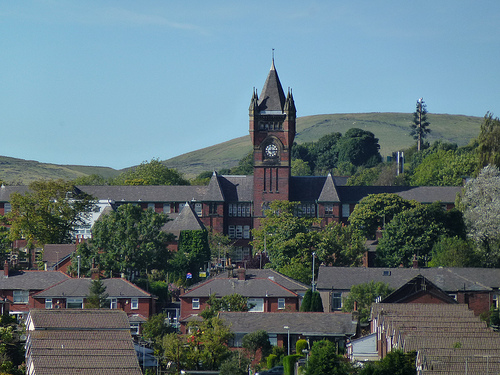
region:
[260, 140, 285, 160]
clock face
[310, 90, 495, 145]
flat green hills to horizon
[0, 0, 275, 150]
bright clear sky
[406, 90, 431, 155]
tall tree standing alone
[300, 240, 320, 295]
telephone pole in street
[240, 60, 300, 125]
clock tower roof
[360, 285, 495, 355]
row of houses in cul de sac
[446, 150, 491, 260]
white leaved tree standing alone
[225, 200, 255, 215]
row of windows on clock tower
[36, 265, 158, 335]
brick house in cul de sac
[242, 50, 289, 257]
a tall clock tower in front of the building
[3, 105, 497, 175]
grassy hills in the background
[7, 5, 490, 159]
the bright blue cloudless sky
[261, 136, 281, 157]
the clock in the tower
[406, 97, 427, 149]
a very tall tree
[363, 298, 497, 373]
a row of homes along a street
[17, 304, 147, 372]
another row of homes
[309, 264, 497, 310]
a big house in the neighborhood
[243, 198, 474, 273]
a group of green leafy trees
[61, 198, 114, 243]
a building with a white roof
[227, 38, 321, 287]
tall clock tower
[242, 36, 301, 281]
big red pointy tower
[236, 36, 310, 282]
red brick clock tower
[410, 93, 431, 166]
very tall tree on hillside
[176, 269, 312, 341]
red brick house with black shingle roof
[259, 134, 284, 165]
large black and white clock on tower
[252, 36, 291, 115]
pointed spire on top of clock tower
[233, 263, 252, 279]
chimney on roof of house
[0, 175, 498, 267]
large building attached to clock tower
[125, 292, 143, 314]
small white window in brick house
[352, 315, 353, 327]
edge of a roof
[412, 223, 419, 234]
edge of a plant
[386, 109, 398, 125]
part of a mountain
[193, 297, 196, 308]
part of a window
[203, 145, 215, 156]
slopes of a mountain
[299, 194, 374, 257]
branches of a tree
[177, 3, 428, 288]
a clock tower outside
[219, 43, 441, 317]
a brick clock tower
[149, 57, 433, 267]
a clock outside a building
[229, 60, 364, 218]
a clock at the top of a building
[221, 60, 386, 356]
a clock at the top of a brick building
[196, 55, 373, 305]
a small outside clock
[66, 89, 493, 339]
a large brick building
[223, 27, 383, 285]
a buiding with a pointed top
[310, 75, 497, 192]
a mountain in the distance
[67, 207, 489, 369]
houses along the street